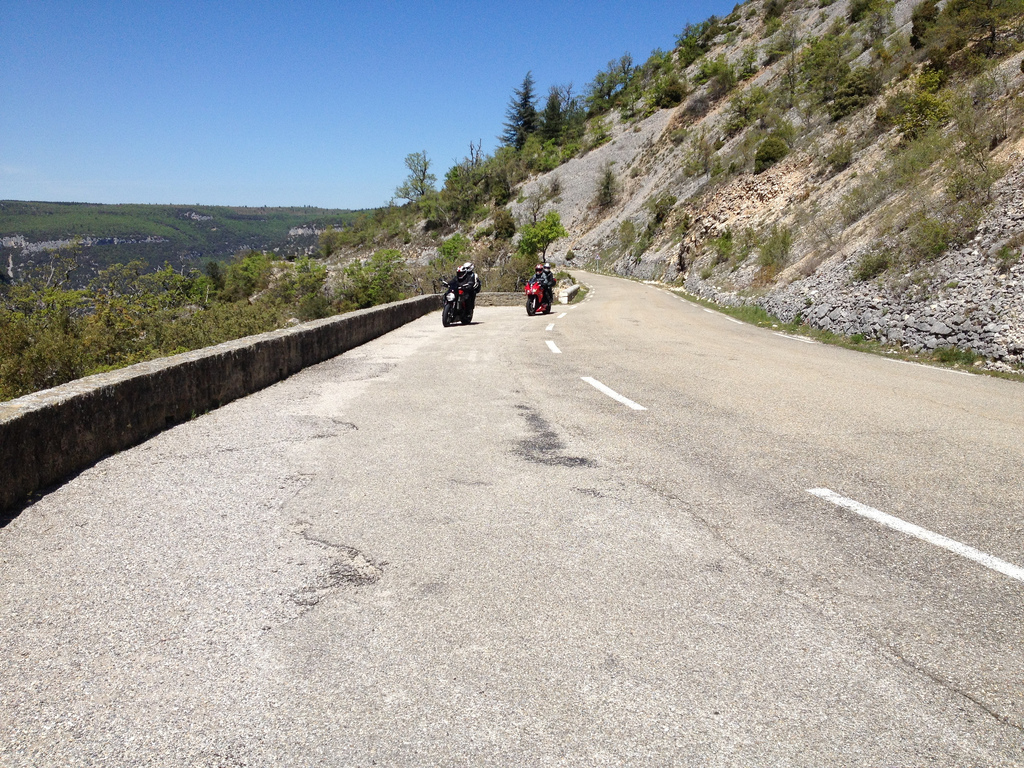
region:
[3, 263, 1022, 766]
road is gray and paved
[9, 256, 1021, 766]
black motorcycle driving on road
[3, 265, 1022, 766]
red motorcycle driving on road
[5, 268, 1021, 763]
white lines painted on road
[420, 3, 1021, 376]
trees on a hill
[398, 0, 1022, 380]
gray rocks on a hill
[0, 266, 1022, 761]
short wall alongside road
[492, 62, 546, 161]
tree is tall and green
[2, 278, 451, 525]
green bushes next to wall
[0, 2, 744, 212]
sky is blue and clear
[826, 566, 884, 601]
asphalt on the ground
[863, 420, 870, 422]
asphalt on the ground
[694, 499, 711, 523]
asphalt on the ground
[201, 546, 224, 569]
asphalt on the ground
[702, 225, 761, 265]
A bush is growing on the side of a mountain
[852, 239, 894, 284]
A bush is growing on the side of a mountain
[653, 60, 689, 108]
A bush is growing on the side of a mountain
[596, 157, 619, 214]
A bush is growing on the side of a mountain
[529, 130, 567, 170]
A bush is growing on the side of a mountain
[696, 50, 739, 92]
A bush is growing on the side of a mountain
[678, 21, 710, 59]
A bush is growing on the side of a mountain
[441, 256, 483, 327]
Black and white motorcycle.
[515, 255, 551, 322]
Red and black motorcycle.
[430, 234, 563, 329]
Two motorcycles on a road.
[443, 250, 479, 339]
Motorcycle driving on a road.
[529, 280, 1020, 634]
White stripes painted on the center of a road.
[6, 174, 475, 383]
Green plants by a road.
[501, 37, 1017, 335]
Hill next to a road.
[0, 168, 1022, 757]
Gray paved road.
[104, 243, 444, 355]
Green bushes next to a road.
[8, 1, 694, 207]
Clear, blue sky above a road and hills.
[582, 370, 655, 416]
a long white painted line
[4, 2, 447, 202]
a blue sky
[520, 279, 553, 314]
a red and black motorcycle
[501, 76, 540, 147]
a tall green tree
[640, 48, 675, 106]
green leaves on the tree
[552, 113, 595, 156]
green leaves on the tree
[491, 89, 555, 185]
green leaves on the tree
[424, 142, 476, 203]
green leaves on the tree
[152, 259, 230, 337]
green leaves on the tree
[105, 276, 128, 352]
green leaves on the tree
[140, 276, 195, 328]
green leaves on the tree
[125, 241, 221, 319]
green leaves on the tree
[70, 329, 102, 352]
green leaves on the tree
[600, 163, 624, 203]
A tree in the woods.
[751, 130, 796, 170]
A tree in the woods.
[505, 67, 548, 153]
A tree in the woods.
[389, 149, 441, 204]
A tree in the woods.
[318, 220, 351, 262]
A tree in the woods.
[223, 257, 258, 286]
A tree in the woods.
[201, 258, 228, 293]
A tree in the woods.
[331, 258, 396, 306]
A tree in the woods.